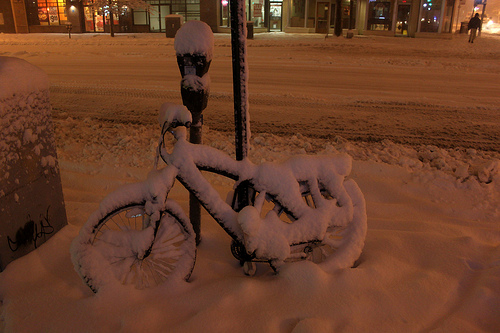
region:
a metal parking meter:
[169, 13, 218, 113]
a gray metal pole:
[183, 113, 208, 245]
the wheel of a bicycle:
[73, 192, 202, 299]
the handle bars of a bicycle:
[153, 99, 207, 136]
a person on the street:
[461, 8, 485, 47]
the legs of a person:
[466, 25, 480, 43]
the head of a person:
[471, 9, 481, 19]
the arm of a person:
[474, 17, 484, 36]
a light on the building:
[66, 1, 78, 12]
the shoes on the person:
[462, 34, 479, 44]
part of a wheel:
[101, 208, 149, 280]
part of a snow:
[393, 230, 430, 285]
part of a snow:
[380, 233, 412, 290]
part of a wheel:
[169, 230, 213, 292]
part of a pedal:
[251, 230, 284, 275]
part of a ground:
[341, 278, 365, 325]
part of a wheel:
[181, 233, 225, 300]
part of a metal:
[228, 205, 262, 272]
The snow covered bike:
[67, 102, 371, 313]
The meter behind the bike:
[172, 12, 218, 246]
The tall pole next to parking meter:
[219, 0, 259, 274]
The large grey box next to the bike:
[1, 51, 75, 272]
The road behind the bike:
[0, 32, 497, 152]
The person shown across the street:
[459, 10, 487, 46]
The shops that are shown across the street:
[2, 0, 473, 37]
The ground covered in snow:
[1, 30, 498, 332]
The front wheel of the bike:
[64, 182, 202, 295]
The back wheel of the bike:
[253, 160, 373, 282]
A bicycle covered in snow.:
[68, 102, 368, 305]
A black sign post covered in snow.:
[227, 0, 251, 158]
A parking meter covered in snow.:
[172, 20, 215, 246]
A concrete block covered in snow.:
[0, 56, 68, 271]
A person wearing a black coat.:
[463, 12, 484, 44]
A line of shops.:
[0, 0, 457, 37]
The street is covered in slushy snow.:
[1, 33, 498, 177]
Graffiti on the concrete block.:
[3, 202, 55, 258]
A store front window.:
[27, 0, 71, 25]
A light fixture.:
[67, 3, 77, 13]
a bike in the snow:
[85, 115, 377, 295]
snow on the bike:
[82, 123, 366, 282]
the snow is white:
[405, 216, 467, 278]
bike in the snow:
[28, 121, 378, 301]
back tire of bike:
[247, 151, 377, 281]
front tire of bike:
[57, 170, 202, 315]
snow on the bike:
[217, 142, 358, 247]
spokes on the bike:
[82, 210, 145, 271]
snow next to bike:
[300, 252, 416, 327]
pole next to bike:
[205, 6, 282, 127]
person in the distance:
[447, 2, 487, 53]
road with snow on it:
[290, 45, 436, 140]